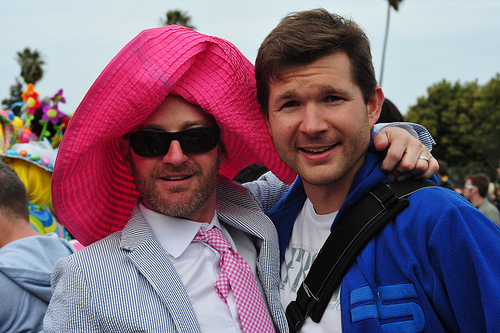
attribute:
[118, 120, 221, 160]
sunglasses — black, pink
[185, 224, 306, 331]
tie — pink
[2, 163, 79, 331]
man — gray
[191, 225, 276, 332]
necktie — pink, white, checkered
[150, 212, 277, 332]
shirt — white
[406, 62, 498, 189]
trees — green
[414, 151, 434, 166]
ring — silver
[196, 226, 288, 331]
tie — pink, white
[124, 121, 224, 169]
sunglasses — dark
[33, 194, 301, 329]
jacket — striped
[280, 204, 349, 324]
shirt — white, gray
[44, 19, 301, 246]
hat — pink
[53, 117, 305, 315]
suit jacket — striped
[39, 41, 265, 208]
hat — pink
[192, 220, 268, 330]
tie — pink